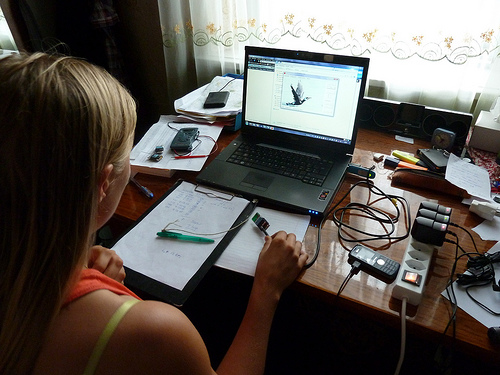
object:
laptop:
[187, 43, 375, 222]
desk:
[97, 63, 497, 321]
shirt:
[60, 269, 143, 304]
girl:
[3, 43, 310, 368]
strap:
[77, 287, 143, 374]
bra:
[80, 293, 144, 375]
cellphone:
[345, 243, 402, 285]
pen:
[154, 224, 218, 247]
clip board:
[103, 173, 259, 300]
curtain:
[158, 0, 498, 129]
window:
[179, 1, 498, 124]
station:
[390, 98, 426, 142]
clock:
[431, 127, 454, 148]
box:
[464, 108, 499, 155]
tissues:
[480, 99, 499, 123]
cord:
[247, 212, 320, 258]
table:
[135, 71, 474, 321]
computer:
[190, 44, 369, 219]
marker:
[380, 153, 425, 173]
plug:
[348, 159, 376, 186]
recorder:
[164, 124, 201, 159]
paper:
[126, 111, 227, 173]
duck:
[284, 80, 311, 110]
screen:
[240, 53, 365, 146]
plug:
[409, 249, 430, 262]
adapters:
[410, 216, 448, 248]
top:
[55, 261, 150, 310]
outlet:
[403, 260, 427, 273]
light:
[402, 270, 417, 283]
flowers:
[441, 44, 452, 50]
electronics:
[199, 89, 231, 114]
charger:
[243, 206, 273, 239]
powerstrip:
[397, 194, 444, 293]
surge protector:
[389, 199, 457, 303]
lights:
[311, 210, 318, 216]